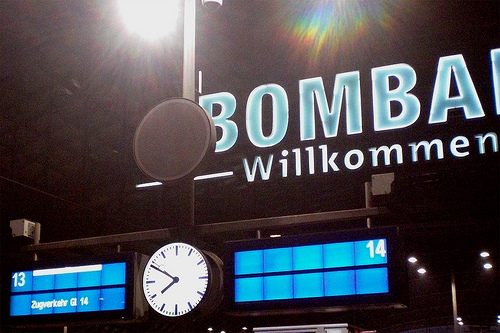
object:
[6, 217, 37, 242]
box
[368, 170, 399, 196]
box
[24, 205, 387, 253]
beam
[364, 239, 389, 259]
14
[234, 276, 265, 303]
squares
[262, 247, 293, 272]
square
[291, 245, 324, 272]
square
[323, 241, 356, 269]
square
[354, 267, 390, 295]
square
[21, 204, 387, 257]
rod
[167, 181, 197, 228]
post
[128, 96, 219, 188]
black light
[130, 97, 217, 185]
circle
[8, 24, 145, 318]
wall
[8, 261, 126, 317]
screen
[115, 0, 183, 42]
light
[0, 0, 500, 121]
roof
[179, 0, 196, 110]
pole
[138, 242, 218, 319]
clock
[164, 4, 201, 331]
pole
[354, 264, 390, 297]
lights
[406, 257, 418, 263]
lights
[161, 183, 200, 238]
pole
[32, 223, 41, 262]
pole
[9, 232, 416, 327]
sign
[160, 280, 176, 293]
clock hand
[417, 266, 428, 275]
lights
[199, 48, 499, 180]
company name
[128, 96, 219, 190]
speaker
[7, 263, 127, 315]
blue screen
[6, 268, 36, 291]
13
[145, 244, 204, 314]
numbers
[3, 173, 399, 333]
building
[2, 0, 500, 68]
ceiling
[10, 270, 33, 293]
first square